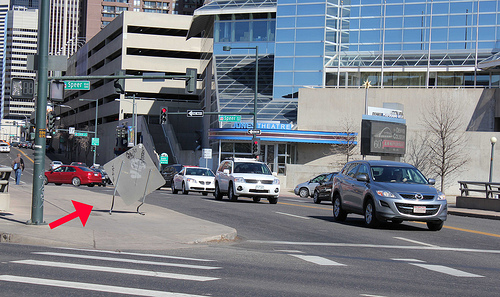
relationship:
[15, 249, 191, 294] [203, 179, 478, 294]
crosswalk on street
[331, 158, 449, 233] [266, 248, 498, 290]
car approaching intersection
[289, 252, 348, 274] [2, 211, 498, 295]
line in street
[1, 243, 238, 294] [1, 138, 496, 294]
stripes on street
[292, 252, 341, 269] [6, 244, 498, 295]
paint on asphalt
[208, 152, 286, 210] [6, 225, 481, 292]
car approaching intersection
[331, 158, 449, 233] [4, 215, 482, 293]
car approaching intersection